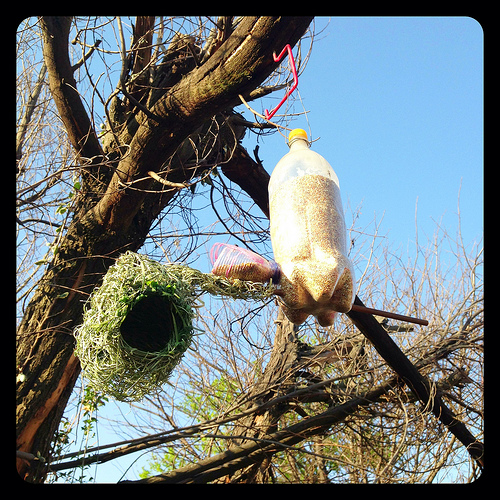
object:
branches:
[59, 13, 171, 111]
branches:
[366, 211, 467, 343]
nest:
[73, 250, 197, 404]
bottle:
[266, 129, 355, 325]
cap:
[285, 127, 308, 144]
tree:
[15, 13, 486, 492]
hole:
[118, 290, 182, 356]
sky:
[15, 16, 486, 484]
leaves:
[58, 177, 351, 475]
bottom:
[284, 284, 354, 326]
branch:
[40, 13, 103, 166]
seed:
[266, 175, 356, 328]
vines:
[15, 12, 483, 483]